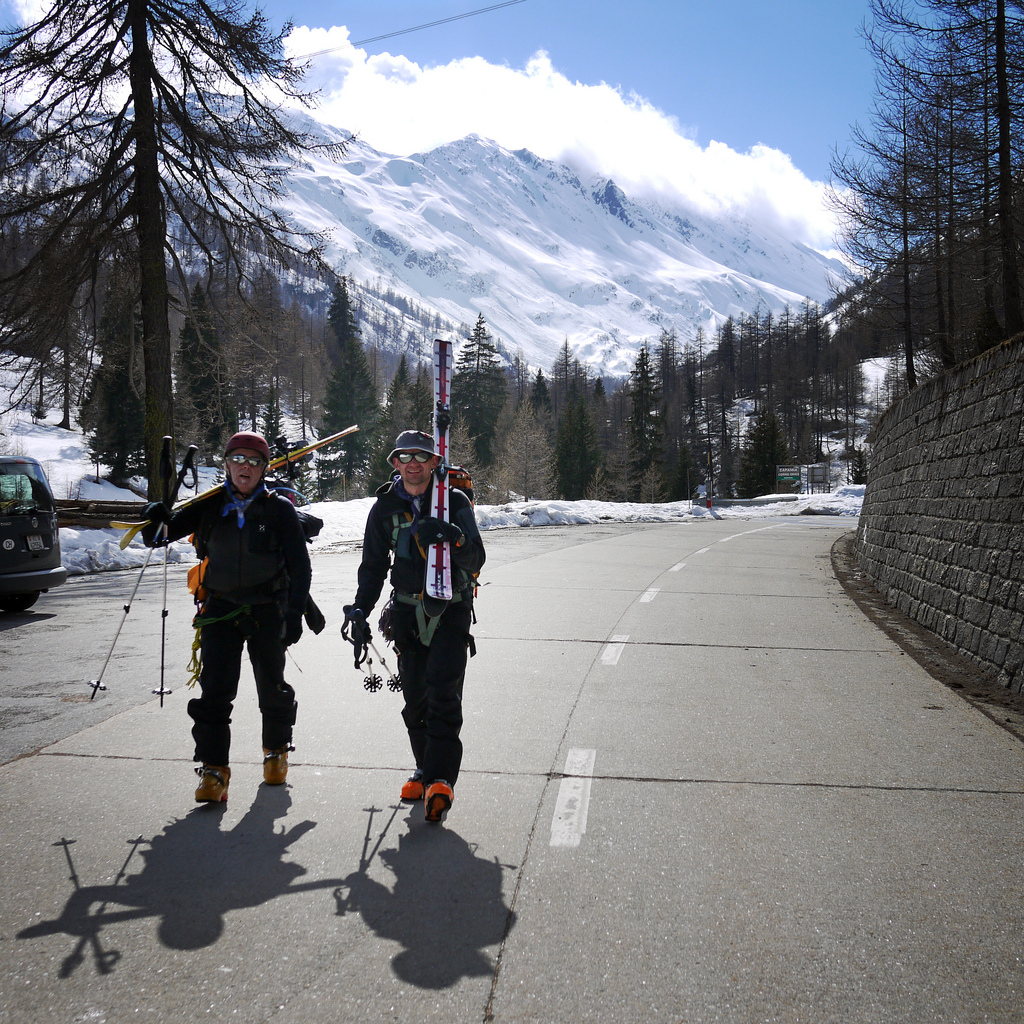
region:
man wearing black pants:
[381, 595, 477, 769]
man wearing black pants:
[192, 606, 301, 747]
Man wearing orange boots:
[395, 767, 460, 821]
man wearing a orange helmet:
[212, 433, 270, 456]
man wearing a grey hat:
[369, 424, 458, 479]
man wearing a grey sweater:
[347, 484, 480, 605]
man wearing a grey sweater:
[148, 480, 313, 626]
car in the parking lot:
[10, 452, 67, 586]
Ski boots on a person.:
[177, 742, 291, 822]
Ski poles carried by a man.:
[70, 433, 213, 708]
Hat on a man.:
[204, 426, 272, 500]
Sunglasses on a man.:
[217, 446, 265, 473]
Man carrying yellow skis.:
[84, 392, 348, 848]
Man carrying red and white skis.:
[359, 336, 483, 839]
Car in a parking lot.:
[6, 448, 80, 617]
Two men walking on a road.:
[97, 412, 512, 818]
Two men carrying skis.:
[154, 374, 557, 871]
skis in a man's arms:
[423, 326, 452, 599]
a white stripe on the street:
[557, 744, 597, 852]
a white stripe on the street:
[592, 623, 634, 658]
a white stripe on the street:
[625, 579, 664, 606]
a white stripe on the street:
[666, 550, 689, 580]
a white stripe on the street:
[694, 531, 710, 552]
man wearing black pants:
[386, 598, 482, 788]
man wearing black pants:
[174, 598, 289, 751]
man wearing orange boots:
[395, 758, 459, 822]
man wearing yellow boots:
[171, 740, 312, 817]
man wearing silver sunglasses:
[394, 442, 434, 466]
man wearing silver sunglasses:
[218, 449, 270, 476]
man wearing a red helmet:
[218, 427, 277, 466]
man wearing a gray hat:
[384, 423, 438, 469]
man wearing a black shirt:
[148, 477, 313, 599]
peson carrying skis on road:
[339, 370, 508, 846]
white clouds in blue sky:
[424, 48, 511, 167]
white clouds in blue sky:
[634, 78, 730, 174]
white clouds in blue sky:
[277, 2, 367, 75]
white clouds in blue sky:
[702, 145, 763, 223]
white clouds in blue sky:
[716, 40, 774, 101]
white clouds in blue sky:
[509, 19, 652, 138]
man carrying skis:
[105, 391, 368, 824]